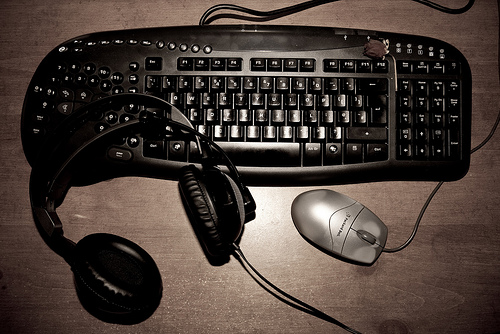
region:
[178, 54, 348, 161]
A keyboard in the photo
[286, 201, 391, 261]
A silver mouse in the photo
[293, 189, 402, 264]
A mouse on the table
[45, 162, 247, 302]
Headphones on the table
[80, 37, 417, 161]
A computer keyboard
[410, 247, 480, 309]
A table in the photo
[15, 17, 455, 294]
A table with keyboard, mouse and headphones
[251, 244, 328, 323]
A wire on the headphones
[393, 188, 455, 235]
A cord on the mouse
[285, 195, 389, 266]
mouse on the desk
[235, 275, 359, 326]
cord for the headphones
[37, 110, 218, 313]
headphones on the desk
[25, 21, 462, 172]
keyboard on the desk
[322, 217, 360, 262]
the mouse is silver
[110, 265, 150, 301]
the headphones are black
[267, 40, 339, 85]
the keyboard is black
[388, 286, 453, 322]
the table is wood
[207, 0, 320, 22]
cord for the keyboard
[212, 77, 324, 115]
keys on the keyboard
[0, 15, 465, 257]
this is a keyboard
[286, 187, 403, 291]
this is a mouse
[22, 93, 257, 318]
these are head phones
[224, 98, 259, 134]
keys on the key board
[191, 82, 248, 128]
keys on the key board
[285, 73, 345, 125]
keys on the key board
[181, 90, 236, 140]
keys on the key board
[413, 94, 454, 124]
keys on the key board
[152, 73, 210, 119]
keys on the key board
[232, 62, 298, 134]
A keyboard in the photo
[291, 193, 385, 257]
A mouse in the photo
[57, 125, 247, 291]
Headphones on the table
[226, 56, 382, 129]
Black keyboard in the photo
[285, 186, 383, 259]
A mouse silver in color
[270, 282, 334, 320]
wire of the headphone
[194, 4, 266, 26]
Cable of a keyboard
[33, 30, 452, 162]
A computer keyboard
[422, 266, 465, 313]
A table in the photo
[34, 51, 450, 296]
Keyboard, mouse and headphones on the table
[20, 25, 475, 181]
keyboard black in color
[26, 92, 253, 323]
black headphones with a microphone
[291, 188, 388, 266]
grey colored mouse on the desk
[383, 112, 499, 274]
grey cord coming from the mouse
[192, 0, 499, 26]
black cord coming from the keyboard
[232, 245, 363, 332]
black cord coming from the headphones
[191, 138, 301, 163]
spacebar on the keyboard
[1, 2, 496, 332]
brown wooden desk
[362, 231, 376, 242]
scroll wheel on the mouse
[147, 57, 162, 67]
escape key on the keyboard